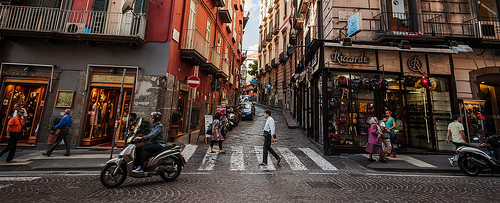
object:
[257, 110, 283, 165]
people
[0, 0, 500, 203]
outdoors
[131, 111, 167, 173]
man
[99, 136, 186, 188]
motorcycle